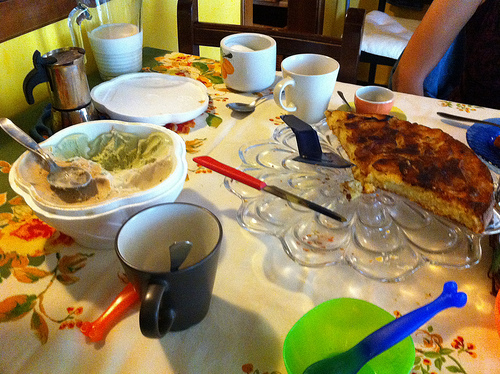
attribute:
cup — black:
[115, 200, 225, 342]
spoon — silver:
[0, 116, 93, 190]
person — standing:
[387, 0, 498, 110]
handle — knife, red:
[192, 155, 268, 195]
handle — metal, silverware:
[436, 110, 499, 132]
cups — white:
[218, 30, 339, 127]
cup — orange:
[354, 83, 396, 117]